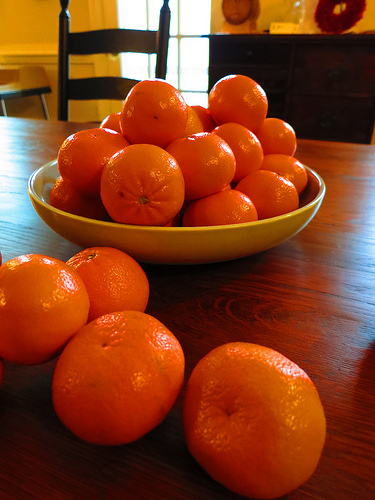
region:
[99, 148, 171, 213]
Bright orange fruit on bowl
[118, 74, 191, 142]
Bright orange fruit on bowl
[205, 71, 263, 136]
Bright orange fruit on bowl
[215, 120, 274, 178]
Bright orange fruit on bowl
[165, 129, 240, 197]
Bright orange fruit on bowl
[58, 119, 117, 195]
Bright orange fruit on bowl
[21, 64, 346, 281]
Bright orange fruit on bowl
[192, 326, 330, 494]
Bright orange fruit on table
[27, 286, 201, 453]
Bright orange fruit on table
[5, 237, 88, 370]
Bright orange fruit on table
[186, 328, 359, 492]
orange sitting on the table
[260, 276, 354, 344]
dark brown wood grained table top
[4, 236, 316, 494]
oranges laying on the table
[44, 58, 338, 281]
bowl of oranges on the table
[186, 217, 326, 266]
yellow bowl on the table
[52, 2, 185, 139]
black ladder back chair at the table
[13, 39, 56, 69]
wood molding on the wall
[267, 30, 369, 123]
dark brown cabinet against the wall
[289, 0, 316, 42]
glass sitting on the cabinet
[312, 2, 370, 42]
wreath on top of the cabinet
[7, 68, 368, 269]
Bowl of navel oranges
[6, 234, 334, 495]
Four oranges lying on table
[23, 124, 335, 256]
Yellow bowl holding oranges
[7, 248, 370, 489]
Dark brown wooden table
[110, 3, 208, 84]
Sunlit window in door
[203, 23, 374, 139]
Dark brown cabinet with drawers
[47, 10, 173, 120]
Dark brown wooden chair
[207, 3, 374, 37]
Decorations on top of cabinet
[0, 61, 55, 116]
Edge of table with metal legs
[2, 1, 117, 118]
Cream colored wall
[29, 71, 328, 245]
a bowl of tangerines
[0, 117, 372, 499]
wooden table top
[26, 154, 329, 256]
a gold bowl holds the tangerines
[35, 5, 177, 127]
black ladder back chair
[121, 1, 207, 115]
small paned winndow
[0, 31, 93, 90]
room has chair rail moulding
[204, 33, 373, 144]
a dark wood buffet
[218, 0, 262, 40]
a wooden barrel on buffet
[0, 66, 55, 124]
an occasional table by window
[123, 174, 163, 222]
end of tangerine that was attached to branch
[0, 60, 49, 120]
Side table by a wall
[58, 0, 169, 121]
Wooden chair by a table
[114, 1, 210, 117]
Window behind a chair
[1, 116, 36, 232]
Light reflecting on a table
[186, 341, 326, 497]
Orange on a table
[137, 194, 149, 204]
Core of an orange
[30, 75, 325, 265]
Oranges stacked in a bowl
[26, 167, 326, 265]
Yellow bowl on a table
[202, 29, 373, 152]
Chest of drawers against a wall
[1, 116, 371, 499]
Brown wooden table top